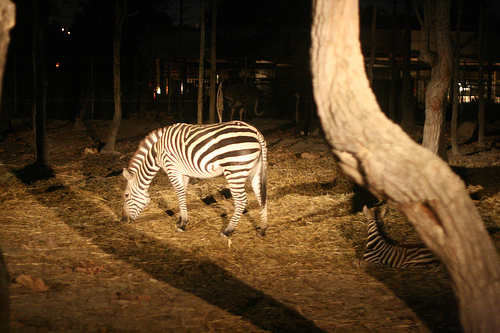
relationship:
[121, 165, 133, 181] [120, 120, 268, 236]
ear of zebra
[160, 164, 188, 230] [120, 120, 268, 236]
leg belonging to zebra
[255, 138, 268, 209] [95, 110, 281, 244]
tail belonging to zebra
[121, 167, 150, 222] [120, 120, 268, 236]
head of zebra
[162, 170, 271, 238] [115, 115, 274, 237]
legs of zebra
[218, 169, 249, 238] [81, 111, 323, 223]
back of zebra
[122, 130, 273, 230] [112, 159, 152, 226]
zebra has head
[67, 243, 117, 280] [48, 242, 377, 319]
hay on ground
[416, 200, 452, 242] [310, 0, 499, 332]
hole on tree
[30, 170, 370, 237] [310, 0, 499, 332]
dirt below tree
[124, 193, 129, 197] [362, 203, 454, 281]
eye of a zebra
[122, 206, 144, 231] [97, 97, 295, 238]
nose of a zebra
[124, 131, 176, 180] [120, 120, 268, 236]
mane of a zebra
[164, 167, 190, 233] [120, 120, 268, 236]
leg of a zebra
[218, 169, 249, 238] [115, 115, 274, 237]
back of zebra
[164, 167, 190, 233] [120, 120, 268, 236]
leg of zebra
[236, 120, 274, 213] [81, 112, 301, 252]
tail of zebra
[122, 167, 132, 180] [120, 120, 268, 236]
ear of zebra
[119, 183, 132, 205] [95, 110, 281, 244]
eye of zebra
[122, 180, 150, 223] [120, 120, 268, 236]
head of zebra